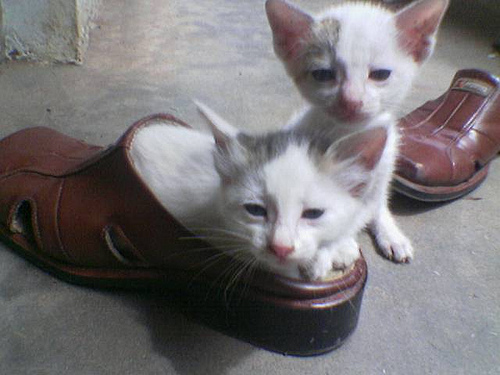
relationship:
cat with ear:
[261, 0, 450, 266] [260, 5, 313, 55]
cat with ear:
[261, 0, 450, 266] [393, 3, 443, 56]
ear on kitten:
[320, 112, 390, 207] [124, 90, 402, 293]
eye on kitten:
[299, 207, 324, 219] [129, 97, 396, 282]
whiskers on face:
[166, 222, 369, 317] [184, 97, 395, 272]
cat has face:
[273, 0, 443, 254] [225, 163, 357, 257]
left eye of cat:
[367, 65, 392, 88] [262, 0, 449, 265]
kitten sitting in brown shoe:
[129, 97, 396, 282] [2, 104, 368, 357]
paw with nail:
[377, 235, 414, 264] [388, 257, 392, 262]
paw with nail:
[377, 235, 414, 264] [402, 258, 406, 263]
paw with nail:
[377, 235, 414, 264] [406, 259, 413, 265]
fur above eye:
[295, 31, 338, 62] [312, 66, 334, 83]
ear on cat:
[397, 6, 442, 57] [262, 0, 449, 265]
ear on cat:
[260, 4, 333, 66] [189, 86, 406, 301]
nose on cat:
[270, 244, 292, 256] [89, 38, 452, 277]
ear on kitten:
[265, 3, 316, 53] [265, 2, 447, 263]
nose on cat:
[269, 240, 294, 259] [130, 98, 389, 319]